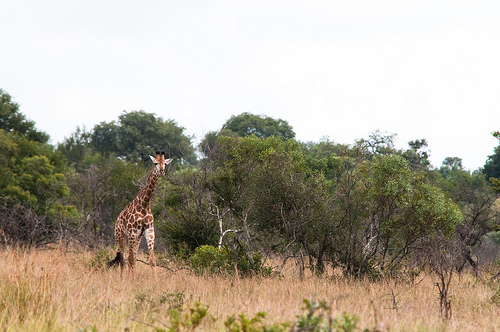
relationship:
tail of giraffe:
[107, 250, 120, 264] [128, 145, 180, 276]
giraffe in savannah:
[128, 145, 180, 276] [2, 278, 404, 319]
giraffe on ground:
[128, 145, 180, 276] [19, 264, 101, 290]